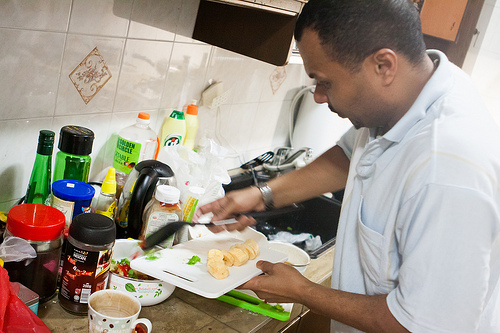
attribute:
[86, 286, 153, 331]
coffee mug — dirty, empty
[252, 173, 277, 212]
watch — silver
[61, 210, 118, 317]
instant coffee — with dark lid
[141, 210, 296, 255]
ladle — black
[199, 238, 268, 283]
banana — sliced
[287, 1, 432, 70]
hair — is dark black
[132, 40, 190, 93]
wall — decorative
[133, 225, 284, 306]
block — white, plastic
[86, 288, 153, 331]
mug — white, spotted, empty, unwashed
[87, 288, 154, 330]
cup — white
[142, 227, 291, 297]
shape — rectangular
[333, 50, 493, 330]
t-shirt — light blue, light, blue